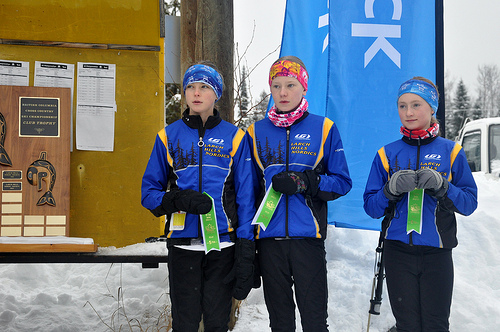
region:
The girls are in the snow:
[5, 30, 495, 325]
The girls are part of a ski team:
[22, 22, 497, 328]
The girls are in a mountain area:
[6, 25, 497, 313]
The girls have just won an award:
[26, 20, 488, 310]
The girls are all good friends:
[15, 20, 480, 318]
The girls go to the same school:
[28, 12, 488, 327]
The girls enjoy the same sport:
[18, 12, 493, 318]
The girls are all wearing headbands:
[11, 20, 497, 327]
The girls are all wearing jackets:
[35, 31, 492, 301]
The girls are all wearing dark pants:
[26, 12, 498, 320]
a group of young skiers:
[132, 54, 482, 329]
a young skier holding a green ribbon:
[356, 72, 480, 330]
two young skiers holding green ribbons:
[139, 52, 356, 328]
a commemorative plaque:
[0, 84, 76, 237]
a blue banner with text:
[279, 1, 438, 228]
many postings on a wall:
[1, 59, 125, 149]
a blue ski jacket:
[360, 134, 482, 249]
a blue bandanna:
[394, 83, 439, 109]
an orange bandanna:
[261, 57, 315, 85]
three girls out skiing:
[132, 58, 493, 330]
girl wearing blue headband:
[382, 67, 465, 147]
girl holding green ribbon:
[394, 162, 442, 254]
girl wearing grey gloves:
[383, 152, 451, 198]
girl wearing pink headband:
[262, 48, 315, 87]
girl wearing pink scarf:
[262, 97, 314, 131]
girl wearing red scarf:
[390, 121, 450, 146]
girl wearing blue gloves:
[268, 151, 320, 202]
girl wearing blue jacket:
[355, 131, 477, 258]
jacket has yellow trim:
[359, 126, 480, 266]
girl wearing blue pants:
[370, 234, 467, 330]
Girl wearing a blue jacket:
[346, 74, 498, 329]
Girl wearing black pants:
[142, 65, 257, 330]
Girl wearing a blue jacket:
[248, 55, 353, 330]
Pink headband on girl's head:
[254, 54, 313, 92]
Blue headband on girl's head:
[175, 60, 225, 97]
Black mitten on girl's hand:
[160, 183, 214, 221]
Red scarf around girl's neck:
[395, 119, 446, 144]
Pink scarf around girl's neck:
[263, 99, 308, 129]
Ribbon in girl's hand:
[250, 177, 282, 232]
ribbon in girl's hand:
[186, 185, 223, 255]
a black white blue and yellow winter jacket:
[139, 123, 254, 243]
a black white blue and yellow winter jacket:
[246, 113, 351, 238]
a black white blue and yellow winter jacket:
[362, 139, 479, 249]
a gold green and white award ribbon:
[198, 192, 223, 249]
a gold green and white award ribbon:
[252, 180, 280, 230]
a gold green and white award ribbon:
[407, 183, 421, 235]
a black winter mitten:
[164, 186, 213, 213]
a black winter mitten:
[272, 170, 317, 192]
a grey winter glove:
[390, 168, 417, 197]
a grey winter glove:
[415, 168, 443, 193]